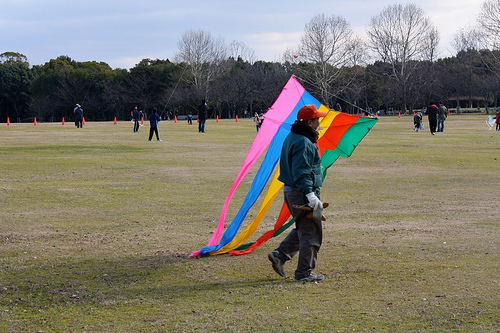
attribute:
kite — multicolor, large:
[189, 74, 379, 258]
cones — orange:
[6, 113, 410, 127]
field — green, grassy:
[0, 117, 499, 332]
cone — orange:
[32, 117, 40, 127]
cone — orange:
[111, 117, 118, 126]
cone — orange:
[214, 114, 219, 121]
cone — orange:
[3, 116, 13, 126]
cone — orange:
[395, 111, 403, 119]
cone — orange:
[233, 114, 241, 122]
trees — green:
[1, 49, 500, 121]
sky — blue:
[1, 0, 499, 71]